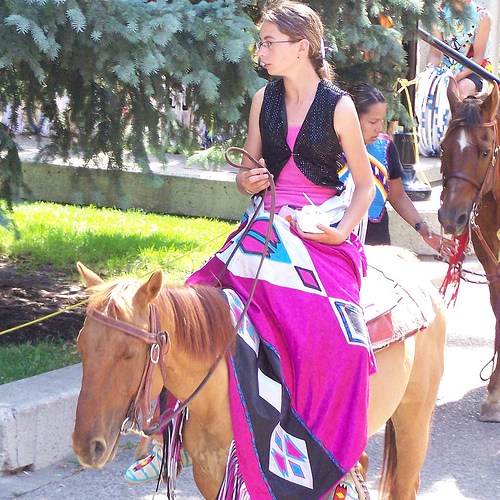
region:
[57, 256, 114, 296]
Ear on a brown pony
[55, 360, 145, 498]
Nose on a brown horse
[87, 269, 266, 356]
Mane on a brown horse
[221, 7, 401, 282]
Girl on a horse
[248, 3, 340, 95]
Brown hair on a woman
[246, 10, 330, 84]
Glasses on a woman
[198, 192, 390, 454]
Pink blanket on a woman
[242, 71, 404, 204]
Black vest on a girl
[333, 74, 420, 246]
Woman leading a horse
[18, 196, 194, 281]
Green grass by pavement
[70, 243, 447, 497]
A horse with a bridal.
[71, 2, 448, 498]
A girl on a horse.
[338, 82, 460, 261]
A girl walking a horse.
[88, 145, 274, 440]
A bridal and reins.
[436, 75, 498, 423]
Part of a horse.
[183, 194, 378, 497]
A pink indian skirt.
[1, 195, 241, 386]
Some bright green grass.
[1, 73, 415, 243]
Part of a pine tree.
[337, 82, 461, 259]
A girl in an indian shirt.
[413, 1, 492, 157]
A girl holding a blanket.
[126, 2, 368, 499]
a girl riding a horse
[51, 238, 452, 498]
horse with a girl above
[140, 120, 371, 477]
a pink dress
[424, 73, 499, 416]
a brown horse in the back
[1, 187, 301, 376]
green grass in the left side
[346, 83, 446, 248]
a girl with blue tshirt touching a horse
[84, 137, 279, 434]
red reins in the horse of the front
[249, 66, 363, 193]
black vest in the girl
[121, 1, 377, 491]
girl looking to the left side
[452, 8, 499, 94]
right hand of a person riding the horse in the back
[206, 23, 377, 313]
The lady is writing a horse.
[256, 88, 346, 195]
The lady is wearing a black vest.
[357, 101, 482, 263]
The lady has her hand on the horse mouth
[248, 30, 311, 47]
The girl is wearing glasses.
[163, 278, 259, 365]
The horse hair is brown.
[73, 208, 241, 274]
The sun is shining on the grass.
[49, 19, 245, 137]
The trees has a lot of leaves.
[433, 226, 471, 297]
A red tassel hanging form the horse mouth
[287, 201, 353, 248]
The girl is holding a cup of ice cream.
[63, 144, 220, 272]
The grass is green.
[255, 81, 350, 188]
black sequined girl's vest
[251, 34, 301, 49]
purple rimmed eye glasses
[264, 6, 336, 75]
long brown straight hair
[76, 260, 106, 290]
brown ear of horse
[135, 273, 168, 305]
brown ear of horse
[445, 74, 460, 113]
brown ear of horse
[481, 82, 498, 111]
brown ear of horse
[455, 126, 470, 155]
white diamond shaped patch on horse head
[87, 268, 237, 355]
brown long horse mane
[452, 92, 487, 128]
brown long horse mane